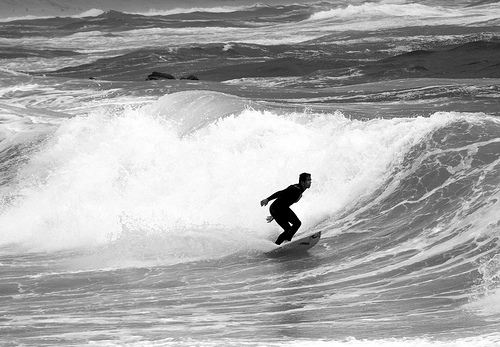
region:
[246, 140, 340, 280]
the man is water surfing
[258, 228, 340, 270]
this is a surf board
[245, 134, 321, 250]
the man is a in a black swim suit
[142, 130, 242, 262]
the water is stirred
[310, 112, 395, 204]
the water is stirred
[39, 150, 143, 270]
the water is stirred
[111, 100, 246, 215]
the water is stirred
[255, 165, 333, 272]
Surfer in the ocean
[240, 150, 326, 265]
Surfer in the ocean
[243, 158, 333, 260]
Surfer in the ocean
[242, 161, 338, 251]
Surfer in the ocean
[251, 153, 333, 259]
Surfer in the ocean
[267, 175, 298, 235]
surfer wearing a wetsuit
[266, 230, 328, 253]
surfboard in the ocean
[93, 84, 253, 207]
waves crashing in the ocean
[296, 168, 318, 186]
man with black hair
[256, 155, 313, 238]
man on a surfboard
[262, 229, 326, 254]
The surfboard the guy is on.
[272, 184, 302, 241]
The wet suit the man is wearing.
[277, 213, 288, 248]
The left leg of the surfer.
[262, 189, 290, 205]
The left arm of the surfer.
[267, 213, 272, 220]
The right hand of the surfer.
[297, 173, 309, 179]
The short hair of the guy.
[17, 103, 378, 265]
The crashing wave behind the guy.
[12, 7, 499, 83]
The water in the distance.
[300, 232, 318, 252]
The design on the bottom of the surfboard.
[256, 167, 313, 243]
man on a surfboard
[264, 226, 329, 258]
white surfboard in the water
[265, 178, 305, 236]
black wetsuit on a surfer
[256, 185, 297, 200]
right arm of a surfer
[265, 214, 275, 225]
left hand of a surfer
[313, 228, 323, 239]
tip of the surfboard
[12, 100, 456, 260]
wave behind the man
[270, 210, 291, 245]
right leg of the man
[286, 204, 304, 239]
left leg of the man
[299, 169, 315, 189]
head of a surfer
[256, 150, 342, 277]
Man in the water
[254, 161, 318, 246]
Man on a surfboard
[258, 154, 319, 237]
Man wearing a black wet suite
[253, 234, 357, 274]
Long white surfboard in the water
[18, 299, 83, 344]
Small ripples in the water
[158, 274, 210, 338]
Small ripples in the water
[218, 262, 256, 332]
Small ripples in the water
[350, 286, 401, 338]
Small ripples in the water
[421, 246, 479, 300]
Small ripples in the water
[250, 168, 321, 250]
surfer on the wave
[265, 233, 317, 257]
surfboard in the water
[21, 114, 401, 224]
white spray on the wave